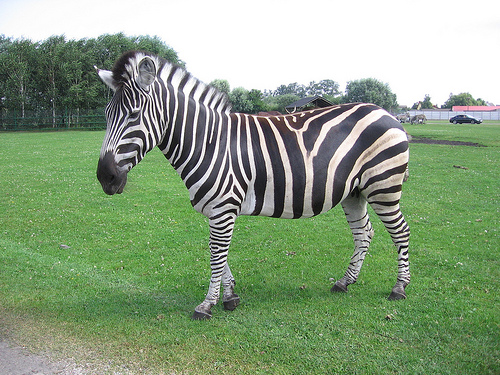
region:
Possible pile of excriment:
[441, 155, 485, 187]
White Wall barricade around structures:
[408, 109, 499, 121]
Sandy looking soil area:
[0, 337, 105, 373]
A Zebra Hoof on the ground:
[324, 256, 361, 306]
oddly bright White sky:
[245, 0, 492, 78]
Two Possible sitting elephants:
[393, 110, 433, 125]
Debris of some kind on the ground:
[378, 307, 412, 336]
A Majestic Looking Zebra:
[81, 40, 443, 328]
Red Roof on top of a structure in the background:
[441, 100, 499, 117]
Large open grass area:
[8, 137, 105, 297]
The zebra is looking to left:
[77, 30, 465, 330]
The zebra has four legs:
[169, 194, 431, 319]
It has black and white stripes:
[235, 132, 307, 200]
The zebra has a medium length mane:
[99, 50, 250, 124]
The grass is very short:
[287, 296, 327, 349]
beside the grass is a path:
[7, 312, 64, 373]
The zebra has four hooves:
[146, 247, 436, 310]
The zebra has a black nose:
[94, 100, 158, 194]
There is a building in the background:
[399, 77, 498, 154]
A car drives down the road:
[447, 100, 488, 138]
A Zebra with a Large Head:
[83, 40, 439, 330]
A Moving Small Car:
[445, 110, 492, 132]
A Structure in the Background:
[404, 105, 499, 117]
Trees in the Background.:
[1, 32, 98, 127]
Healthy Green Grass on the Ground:
[1, 204, 173, 286]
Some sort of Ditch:
[407, 126, 486, 148]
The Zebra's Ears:
[90, 53, 184, 100]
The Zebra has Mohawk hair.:
[103, 42, 250, 117]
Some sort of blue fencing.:
[1, 105, 106, 136]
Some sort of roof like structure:
[278, 87, 341, 109]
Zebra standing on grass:
[79, 56, 446, 341]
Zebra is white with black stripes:
[82, 36, 438, 342]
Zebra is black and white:
[83, 51, 445, 343]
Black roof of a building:
[286, 93, 336, 119]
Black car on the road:
[448, 111, 482, 131]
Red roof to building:
[452, 98, 499, 113]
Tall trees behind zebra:
[6, 33, 196, 158]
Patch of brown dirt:
[411, 120, 487, 165]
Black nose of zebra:
[90, 146, 136, 207]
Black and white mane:
[118, 51, 233, 118]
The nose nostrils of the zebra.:
[92, 165, 120, 187]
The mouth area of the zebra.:
[106, 171, 128, 198]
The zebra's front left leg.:
[198, 224, 244, 307]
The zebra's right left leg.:
[201, 210, 230, 319]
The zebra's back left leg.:
[339, 199, 373, 284]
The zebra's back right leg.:
[372, 190, 426, 301]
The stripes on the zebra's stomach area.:
[225, 114, 350, 219]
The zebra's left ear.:
[90, 63, 120, 87]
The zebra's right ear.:
[135, 55, 163, 83]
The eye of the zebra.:
[127, 104, 148, 123]